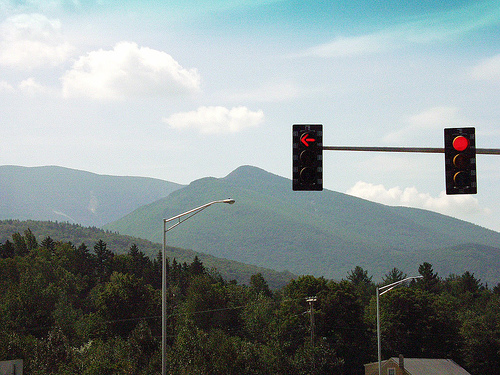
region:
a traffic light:
[271, 101, 434, 336]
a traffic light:
[270, 118, 351, 338]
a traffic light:
[243, 84, 340, 292]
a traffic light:
[292, 30, 407, 273]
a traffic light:
[217, 25, 376, 348]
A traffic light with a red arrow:
[284, 120, 331, 192]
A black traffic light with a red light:
[435, 123, 484, 195]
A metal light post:
[152, 192, 240, 369]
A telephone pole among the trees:
[291, 288, 326, 348]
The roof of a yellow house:
[360, 352, 462, 373]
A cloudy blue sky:
[24, 1, 412, 127]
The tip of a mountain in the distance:
[187, 154, 291, 189]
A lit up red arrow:
[296, 132, 321, 149]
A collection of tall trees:
[2, 222, 247, 360]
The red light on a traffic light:
[448, 131, 473, 153]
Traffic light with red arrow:
[291, 122, 326, 193]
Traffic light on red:
[441, 126, 477, 198]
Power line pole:
[303, 293, 319, 345]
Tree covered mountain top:
[253, 196, 468, 251]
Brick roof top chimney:
[395, 351, 403, 366]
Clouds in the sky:
[6, 75, 283, 157]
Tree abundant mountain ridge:
[2, 213, 154, 244]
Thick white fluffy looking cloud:
[356, 182, 381, 194]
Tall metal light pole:
[160, 215, 167, 371]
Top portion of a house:
[361, 353, 472, 374]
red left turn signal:
[292, 120, 325, 188]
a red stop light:
[442, 127, 482, 196]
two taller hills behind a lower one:
[0, 162, 498, 277]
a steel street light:
[153, 182, 237, 374]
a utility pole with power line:
[15, 291, 355, 373]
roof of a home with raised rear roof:
[361, 352, 478, 374]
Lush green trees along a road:
[32, 234, 157, 374]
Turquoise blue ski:
[153, 1, 465, 39]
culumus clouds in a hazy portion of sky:
[4, 8, 264, 170]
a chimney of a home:
[396, 348, 411, 373]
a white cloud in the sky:
[160, 102, 272, 140]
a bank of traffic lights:
[284, 117, 330, 201]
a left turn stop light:
[295, 128, 321, 150]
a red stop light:
[449, 131, 476, 154]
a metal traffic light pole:
[321, 141, 498, 164]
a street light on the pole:
[218, 191, 243, 211]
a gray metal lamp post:
[156, 212, 175, 374]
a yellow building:
[361, 350, 472, 374]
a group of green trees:
[1, 220, 498, 372]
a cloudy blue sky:
[1, 0, 498, 237]